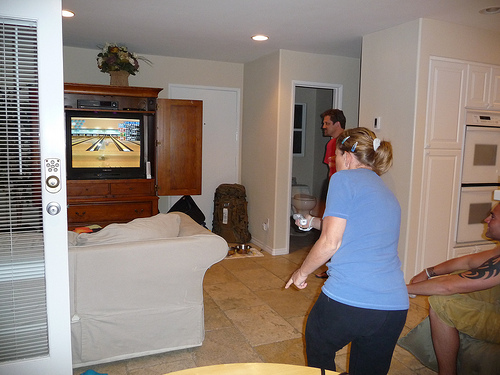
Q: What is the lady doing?
A: Playing Wii.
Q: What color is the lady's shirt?
A: Blue.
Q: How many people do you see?
A: 3.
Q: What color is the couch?
A: White.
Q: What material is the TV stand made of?
A: Wood.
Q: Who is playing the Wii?
A: The woman.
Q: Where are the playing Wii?
A: Living room.